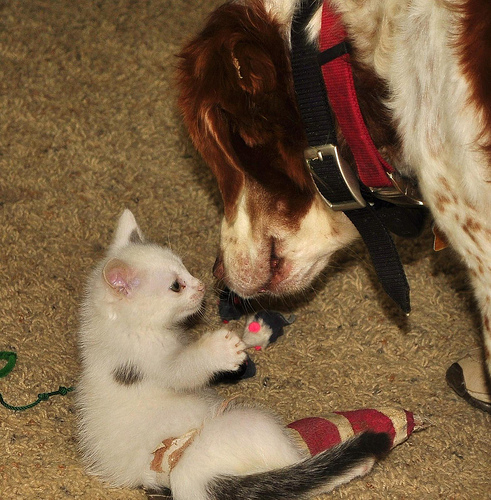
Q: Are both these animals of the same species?
A: No, they are dogs and cats.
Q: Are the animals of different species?
A: Yes, they are dogs and cats.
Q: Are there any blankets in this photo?
A: No, there are no blankets.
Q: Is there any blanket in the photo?
A: No, there are no blankets.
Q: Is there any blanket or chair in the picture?
A: No, there are no blankets or chairs.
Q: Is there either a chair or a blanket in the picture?
A: No, there are no blankets or chairs.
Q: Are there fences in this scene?
A: No, there are no fences.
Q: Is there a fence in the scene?
A: No, there are no fences.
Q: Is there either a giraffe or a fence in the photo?
A: No, there are no fences or giraffes.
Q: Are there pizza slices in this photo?
A: No, there are no pizza slices.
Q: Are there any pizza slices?
A: No, there are no pizza slices.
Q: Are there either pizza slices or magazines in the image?
A: No, there are no pizza slices or magazines.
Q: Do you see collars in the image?
A: Yes, there is a collar.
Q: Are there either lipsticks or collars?
A: Yes, there is a collar.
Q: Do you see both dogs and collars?
A: Yes, there are both a collar and a dog.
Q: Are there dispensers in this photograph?
A: No, there are no dispensers.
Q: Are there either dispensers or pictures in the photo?
A: No, there are no dispensers or pictures.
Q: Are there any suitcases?
A: No, there are no suitcases.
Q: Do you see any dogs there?
A: Yes, there is a dog.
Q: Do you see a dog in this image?
A: Yes, there is a dog.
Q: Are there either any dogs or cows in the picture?
A: Yes, there is a dog.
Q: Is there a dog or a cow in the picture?
A: Yes, there is a dog.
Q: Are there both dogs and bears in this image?
A: No, there is a dog but no bears.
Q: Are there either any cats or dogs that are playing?
A: Yes, the dog is playing.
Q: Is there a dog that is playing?
A: Yes, there is a dog that is playing.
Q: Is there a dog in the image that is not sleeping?
A: Yes, there is a dog that is playing.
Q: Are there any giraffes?
A: No, there are no giraffes.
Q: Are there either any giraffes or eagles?
A: No, there are no giraffes or eagles.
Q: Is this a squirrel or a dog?
A: This is a dog.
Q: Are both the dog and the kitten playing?
A: Yes, both the dog and the kitten are playing.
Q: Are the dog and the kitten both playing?
A: Yes, both the dog and the kitten are playing.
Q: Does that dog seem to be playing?
A: Yes, the dog is playing.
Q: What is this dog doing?
A: The dog is playing.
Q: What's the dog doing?
A: The dog is playing.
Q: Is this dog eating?
A: No, the dog is playing.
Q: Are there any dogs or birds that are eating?
A: No, there is a dog but it is playing.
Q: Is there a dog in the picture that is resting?
A: No, there is a dog but it is playing.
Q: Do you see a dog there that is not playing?
A: No, there is a dog but it is playing.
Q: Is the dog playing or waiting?
A: The dog is playing.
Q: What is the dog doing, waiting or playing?
A: The dog is playing.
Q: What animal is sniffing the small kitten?
A: The dog is sniffing the kitten.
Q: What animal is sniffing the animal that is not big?
A: The dog is sniffing the kitten.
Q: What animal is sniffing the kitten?
A: The dog is sniffing the kitten.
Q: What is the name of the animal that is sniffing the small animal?
A: The animal is a dog.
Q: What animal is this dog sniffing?
A: The dog is sniffing the kitten.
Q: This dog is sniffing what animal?
A: The dog is sniffing the kitten.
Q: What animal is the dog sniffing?
A: The dog is sniffing the kitten.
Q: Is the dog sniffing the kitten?
A: Yes, the dog is sniffing the kitten.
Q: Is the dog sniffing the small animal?
A: Yes, the dog is sniffing the kitten.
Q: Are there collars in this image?
A: Yes, there is a collar.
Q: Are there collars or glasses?
A: Yes, there is a collar.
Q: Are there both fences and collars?
A: No, there is a collar but no fences.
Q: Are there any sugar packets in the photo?
A: No, there are no sugar packets.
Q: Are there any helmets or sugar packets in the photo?
A: No, there are no sugar packets or helmets.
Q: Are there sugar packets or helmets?
A: No, there are no sugar packets or helmets.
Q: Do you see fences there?
A: No, there are no fences.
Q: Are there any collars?
A: Yes, there is a collar.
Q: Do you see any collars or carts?
A: Yes, there is a collar.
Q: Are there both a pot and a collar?
A: No, there is a collar but no pots.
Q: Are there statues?
A: No, there are no statues.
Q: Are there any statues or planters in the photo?
A: No, there are no statues or planters.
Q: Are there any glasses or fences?
A: No, there are no fences or glasses.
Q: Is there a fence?
A: No, there are no fences.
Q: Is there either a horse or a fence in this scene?
A: No, there are no fences or horses.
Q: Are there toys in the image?
A: Yes, there is a toy.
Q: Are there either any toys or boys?
A: Yes, there is a toy.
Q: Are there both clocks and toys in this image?
A: No, there is a toy but no clocks.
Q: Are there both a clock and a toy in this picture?
A: No, there is a toy but no clocks.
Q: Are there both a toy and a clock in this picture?
A: No, there is a toy but no clocks.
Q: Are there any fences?
A: No, there are no fences.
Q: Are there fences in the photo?
A: No, there are no fences.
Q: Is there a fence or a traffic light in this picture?
A: No, there are no fences or traffic lights.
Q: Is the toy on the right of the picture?
A: Yes, the toy is on the right of the image.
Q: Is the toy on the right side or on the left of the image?
A: The toy is on the right of the image.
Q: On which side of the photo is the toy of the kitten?
A: The toy is on the right of the image.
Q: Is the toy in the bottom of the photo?
A: Yes, the toy is in the bottom of the image.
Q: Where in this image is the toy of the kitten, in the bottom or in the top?
A: The toy is in the bottom of the image.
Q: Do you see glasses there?
A: No, there are no glasses.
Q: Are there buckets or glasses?
A: No, there are no glasses or buckets.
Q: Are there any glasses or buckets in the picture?
A: No, there are no glasses or buckets.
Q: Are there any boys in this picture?
A: No, there are no boys.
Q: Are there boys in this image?
A: No, there are no boys.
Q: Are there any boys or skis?
A: No, there are no boys or skis.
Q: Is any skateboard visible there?
A: No, there are no skateboards.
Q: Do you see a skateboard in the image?
A: No, there are no skateboards.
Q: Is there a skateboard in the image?
A: No, there are no skateboards.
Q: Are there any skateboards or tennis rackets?
A: No, there are no skateboards or tennis rackets.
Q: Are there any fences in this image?
A: No, there are no fences.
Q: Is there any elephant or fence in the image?
A: No, there are no fences or elephants.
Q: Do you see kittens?
A: Yes, there is a kitten.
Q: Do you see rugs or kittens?
A: Yes, there is a kitten.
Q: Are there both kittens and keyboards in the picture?
A: No, there is a kitten but no keyboards.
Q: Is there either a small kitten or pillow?
A: Yes, there is a small kitten.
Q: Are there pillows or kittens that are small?
A: Yes, the kitten is small.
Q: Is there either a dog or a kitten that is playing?
A: Yes, the kitten is playing.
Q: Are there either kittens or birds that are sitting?
A: Yes, the kitten is sitting.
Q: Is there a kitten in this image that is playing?
A: Yes, there is a kitten that is playing.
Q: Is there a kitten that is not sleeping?
A: Yes, there is a kitten that is playing.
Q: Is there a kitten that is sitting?
A: Yes, there is a kitten that is sitting.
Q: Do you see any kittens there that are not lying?
A: Yes, there is a kitten that is sitting .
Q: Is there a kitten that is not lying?
A: Yes, there is a kitten that is sitting.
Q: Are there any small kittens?
A: Yes, there is a small kitten.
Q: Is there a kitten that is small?
A: Yes, there is a kitten that is small.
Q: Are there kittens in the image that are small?
A: Yes, there is a kitten that is small.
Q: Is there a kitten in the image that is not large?
A: Yes, there is a small kitten.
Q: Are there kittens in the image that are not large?
A: Yes, there is a small kitten.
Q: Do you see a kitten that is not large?
A: Yes, there is a small kitten.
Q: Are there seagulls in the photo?
A: No, there are no seagulls.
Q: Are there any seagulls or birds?
A: No, there are no seagulls or birds.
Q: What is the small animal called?
A: The animal is a kitten.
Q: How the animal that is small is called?
A: The animal is a kitten.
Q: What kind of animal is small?
A: The animal is a kitten.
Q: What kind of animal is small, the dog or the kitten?
A: The kitten is small.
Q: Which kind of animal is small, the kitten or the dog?
A: The kitten is small.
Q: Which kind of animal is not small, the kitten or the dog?
A: The dog is not small.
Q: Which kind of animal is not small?
A: The animal is a dog.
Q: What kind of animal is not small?
A: The animal is a dog.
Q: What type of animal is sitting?
A: The animal is a kitten.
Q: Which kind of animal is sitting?
A: The animal is a kitten.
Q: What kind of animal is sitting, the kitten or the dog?
A: The kitten is sitting.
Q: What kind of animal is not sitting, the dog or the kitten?
A: The dog is not sitting.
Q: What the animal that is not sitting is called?
A: The animal is a dog.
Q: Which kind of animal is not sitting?
A: The animal is a dog.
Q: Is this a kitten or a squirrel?
A: This is a kitten.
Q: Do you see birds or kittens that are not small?
A: No, there is a kitten but it is small.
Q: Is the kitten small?
A: Yes, the kitten is small.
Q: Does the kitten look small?
A: Yes, the kitten is small.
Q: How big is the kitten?
A: The kitten is small.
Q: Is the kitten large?
A: No, the kitten is small.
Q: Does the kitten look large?
A: No, the kitten is small.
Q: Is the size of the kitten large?
A: No, the kitten is small.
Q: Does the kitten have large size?
A: No, the kitten is small.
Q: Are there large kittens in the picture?
A: No, there is a kitten but it is small.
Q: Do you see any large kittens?
A: No, there is a kitten but it is small.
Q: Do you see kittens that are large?
A: No, there is a kitten but it is small.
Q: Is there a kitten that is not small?
A: No, there is a kitten but it is small.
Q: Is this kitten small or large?
A: The kitten is small.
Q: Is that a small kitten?
A: Yes, that is a small kitten.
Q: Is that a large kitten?
A: No, that is a small kitten.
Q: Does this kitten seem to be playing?
A: Yes, the kitten is playing.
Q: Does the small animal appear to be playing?
A: Yes, the kitten is playing.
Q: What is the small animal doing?
A: The kitten is playing.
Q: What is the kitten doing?
A: The kitten is playing.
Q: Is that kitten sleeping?
A: No, the kitten is playing.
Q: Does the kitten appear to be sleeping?
A: No, the kitten is playing.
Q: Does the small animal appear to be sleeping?
A: No, the kitten is playing.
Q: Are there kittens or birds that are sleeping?
A: No, there is a kitten but it is playing.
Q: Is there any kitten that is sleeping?
A: No, there is a kitten but it is playing.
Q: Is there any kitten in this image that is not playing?
A: No, there is a kitten but it is playing.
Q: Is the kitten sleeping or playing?
A: The kitten is playing.